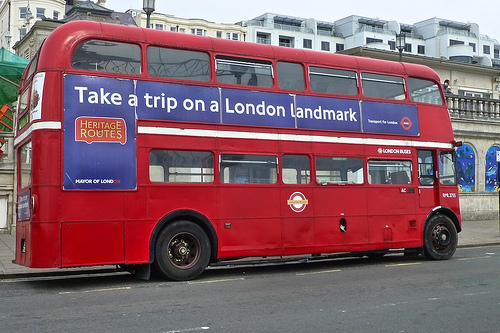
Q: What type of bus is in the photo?
A: Double decker.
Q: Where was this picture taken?
A: London.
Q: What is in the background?
A: Buildings.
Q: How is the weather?
A: Overcast.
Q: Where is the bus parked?
A: On the road.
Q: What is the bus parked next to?
A: The sidewalk.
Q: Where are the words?
A: On sign.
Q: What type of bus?
A: Double decker.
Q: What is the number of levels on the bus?
A: Two.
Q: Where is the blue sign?
A: On the side of the bus.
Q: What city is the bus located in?
A: London.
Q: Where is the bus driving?
A: On the road.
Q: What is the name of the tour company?
A: Heritage Routes.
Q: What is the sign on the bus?
A: An advertisement.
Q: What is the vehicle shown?
A: A double-decker bus.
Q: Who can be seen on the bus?
A: Zero people.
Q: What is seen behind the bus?
A: Buildings.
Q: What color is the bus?
A: Red.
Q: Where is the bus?
A: On the road.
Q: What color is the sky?
A: Blue.